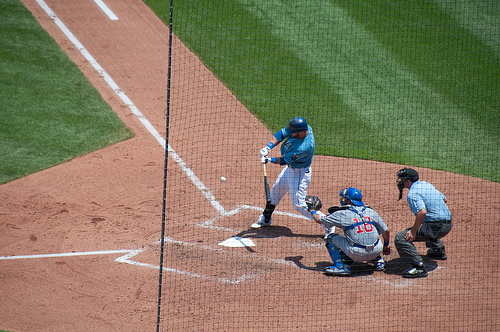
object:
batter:
[248, 114, 327, 233]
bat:
[260, 155, 272, 207]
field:
[0, 1, 499, 332]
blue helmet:
[283, 117, 309, 135]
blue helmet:
[336, 186, 366, 206]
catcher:
[301, 186, 393, 278]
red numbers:
[350, 217, 363, 234]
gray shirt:
[316, 203, 390, 249]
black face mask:
[394, 168, 409, 201]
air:
[40, 171, 108, 203]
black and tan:
[262, 176, 271, 207]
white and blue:
[257, 147, 271, 166]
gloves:
[257, 144, 271, 155]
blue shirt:
[403, 180, 452, 224]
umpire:
[393, 166, 455, 279]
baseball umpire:
[391, 167, 454, 280]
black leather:
[302, 195, 322, 213]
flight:
[216, 116, 327, 230]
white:
[214, 235, 256, 249]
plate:
[230, 234, 257, 253]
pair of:
[322, 232, 387, 268]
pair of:
[267, 165, 325, 220]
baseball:
[218, 175, 228, 184]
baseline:
[154, 2, 176, 331]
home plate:
[114, 203, 449, 290]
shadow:
[233, 223, 328, 240]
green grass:
[0, 0, 138, 185]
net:
[155, 0, 499, 331]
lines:
[32, 0, 168, 149]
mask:
[337, 193, 352, 207]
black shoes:
[399, 257, 429, 279]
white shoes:
[250, 213, 275, 228]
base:
[0, 137, 499, 331]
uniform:
[320, 203, 390, 267]